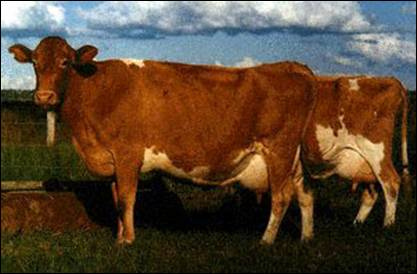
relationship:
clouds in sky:
[86, 6, 373, 33] [34, 4, 406, 70]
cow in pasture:
[313, 65, 416, 225] [5, 145, 416, 272]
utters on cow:
[345, 160, 387, 193] [292, 68, 414, 234]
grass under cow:
[36, 200, 114, 259] [9, 32, 316, 238]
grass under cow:
[36, 200, 114, 259] [281, 61, 416, 236]